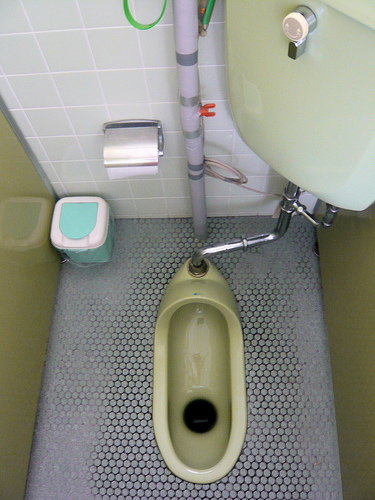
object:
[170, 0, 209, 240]
pipe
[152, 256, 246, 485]
bowl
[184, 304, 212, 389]
water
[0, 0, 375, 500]
bathroom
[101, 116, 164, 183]
holder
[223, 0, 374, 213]
toilet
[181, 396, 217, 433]
hole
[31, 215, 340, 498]
floor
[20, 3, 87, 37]
tile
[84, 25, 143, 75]
tile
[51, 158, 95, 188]
tile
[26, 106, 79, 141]
tile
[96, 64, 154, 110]
tile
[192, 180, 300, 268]
pipe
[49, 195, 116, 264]
receptacle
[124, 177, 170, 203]
tile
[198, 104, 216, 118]
knob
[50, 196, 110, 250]
lid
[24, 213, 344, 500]
ground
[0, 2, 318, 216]
wall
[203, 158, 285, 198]
cord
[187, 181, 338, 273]
pipe